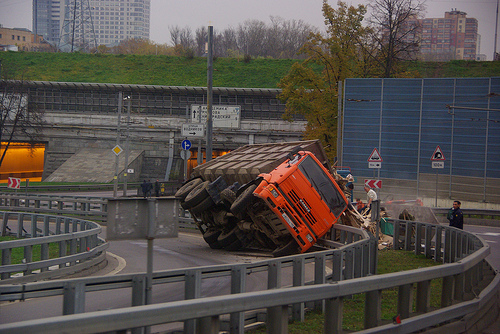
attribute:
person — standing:
[444, 200, 464, 229]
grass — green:
[1, 48, 499, 96]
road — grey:
[2, 206, 333, 332]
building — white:
[32, 0, 148, 55]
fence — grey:
[340, 80, 498, 224]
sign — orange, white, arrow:
[8, 174, 19, 191]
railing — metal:
[0, 208, 105, 288]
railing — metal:
[3, 193, 377, 334]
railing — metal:
[0, 207, 497, 331]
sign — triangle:
[368, 148, 382, 163]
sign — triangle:
[431, 146, 448, 163]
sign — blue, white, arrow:
[182, 138, 190, 152]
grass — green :
[272, 223, 466, 332]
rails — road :
[59, 260, 222, 330]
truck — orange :
[206, 152, 341, 233]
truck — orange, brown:
[173, 137, 349, 255]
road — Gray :
[100, 193, 231, 330]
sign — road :
[426, 140, 451, 171]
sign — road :
[191, 101, 242, 133]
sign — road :
[180, 119, 205, 138]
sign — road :
[180, 137, 190, 151]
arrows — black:
[184, 106, 200, 138]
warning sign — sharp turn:
[3, 177, 23, 191]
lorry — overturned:
[172, 136, 347, 258]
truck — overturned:
[127, 135, 357, 266]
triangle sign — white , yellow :
[367, 147, 383, 168]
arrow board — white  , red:
[4, 173, 23, 193]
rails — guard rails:
[158, 250, 400, 324]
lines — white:
[93, 249, 136, 279]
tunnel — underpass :
[9, 133, 81, 188]